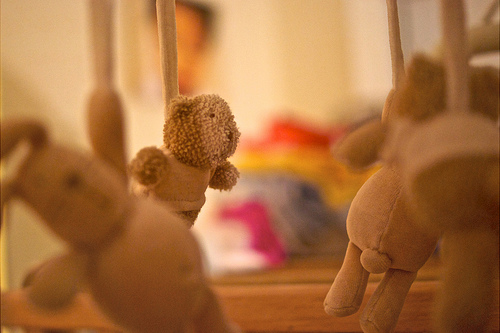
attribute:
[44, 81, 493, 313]
toys — stuffed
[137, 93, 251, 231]
bear — tiny 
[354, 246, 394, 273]
tail — short , stubby 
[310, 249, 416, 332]
legs — stuffed 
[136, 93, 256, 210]
bear — teddy , brown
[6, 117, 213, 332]
bear — brown, teddy 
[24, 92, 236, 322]
bear — teddy , brown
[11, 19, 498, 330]
bears — small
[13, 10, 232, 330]
bears — small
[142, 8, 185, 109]
stick — one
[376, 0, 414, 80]
stick — one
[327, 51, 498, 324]
bears — small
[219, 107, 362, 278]
clothes — piled 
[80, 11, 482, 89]
straps — some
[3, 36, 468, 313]
animals — stuffed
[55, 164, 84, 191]
nose — toy, one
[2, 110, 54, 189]
ears — toy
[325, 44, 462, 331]
animal — stuffed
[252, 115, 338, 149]
clothing — red, folded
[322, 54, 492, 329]
animal — stuffed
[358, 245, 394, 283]
tail — round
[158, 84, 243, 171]
head — bear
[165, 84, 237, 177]
texture — different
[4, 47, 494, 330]
animals — stuffed, strange, surreal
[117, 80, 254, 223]
animal — stuffed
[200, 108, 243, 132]
eyes — small, beady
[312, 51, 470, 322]
animal — stuffed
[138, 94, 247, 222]
bear — brown , stuffed , teddy 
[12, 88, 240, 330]
bunny — stuffed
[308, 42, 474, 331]
bunny — stuffed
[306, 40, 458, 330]
bunny — stuffed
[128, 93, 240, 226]
teddy bear — hanging, brown, small, stuffed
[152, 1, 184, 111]
rope — brown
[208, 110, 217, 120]
eye — black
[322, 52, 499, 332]
teddy bear — hanging, brown, stuffed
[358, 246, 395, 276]
tail — brown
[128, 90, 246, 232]
teddy bear — hanging, brown, stuffed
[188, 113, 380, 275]
object — rainbow colored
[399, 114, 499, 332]
teddy bear — stuffed, brown, hanging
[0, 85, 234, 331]
teddy bear — brown